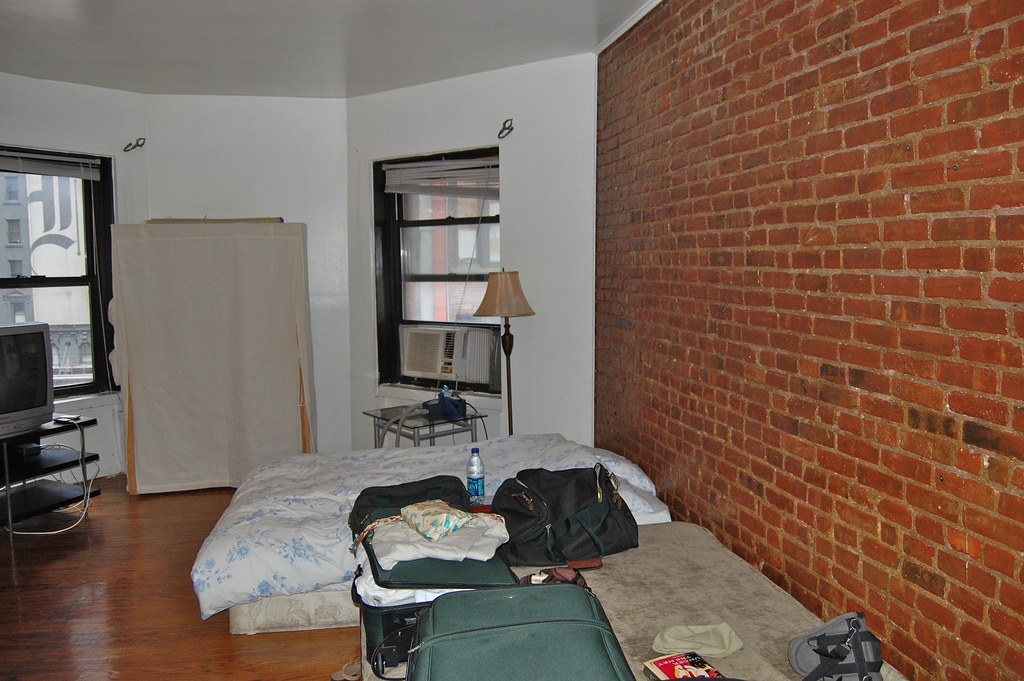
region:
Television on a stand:
[2, 309, 97, 528]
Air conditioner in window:
[371, 150, 502, 395]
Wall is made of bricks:
[593, 1, 1012, 670]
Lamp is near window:
[377, 156, 532, 419]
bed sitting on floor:
[1, 435, 690, 673]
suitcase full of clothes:
[337, 473, 519, 670]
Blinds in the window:
[365, 150, 502, 391]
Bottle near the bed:
[462, 441, 485, 509]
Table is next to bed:
[225, 387, 672, 629]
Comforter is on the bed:
[190, 432, 675, 635]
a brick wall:
[709, 136, 1011, 418]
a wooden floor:
[82, 579, 168, 677]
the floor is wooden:
[73, 570, 156, 676]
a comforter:
[259, 491, 332, 571]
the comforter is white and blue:
[241, 482, 302, 560]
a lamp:
[474, 269, 532, 324]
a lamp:
[470, 264, 548, 432]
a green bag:
[508, 471, 617, 548]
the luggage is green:
[431, 589, 594, 679]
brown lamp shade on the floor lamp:
[476, 265, 535, 322]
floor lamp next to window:
[470, 265, 538, 437]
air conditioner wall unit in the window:
[395, 316, 509, 393]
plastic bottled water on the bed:
[464, 446, 490, 503]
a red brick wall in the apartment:
[596, 2, 1023, 651]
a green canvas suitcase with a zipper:
[408, 582, 639, 678]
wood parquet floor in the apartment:
[85, 496, 193, 678]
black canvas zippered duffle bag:
[486, 461, 642, 566]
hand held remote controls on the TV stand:
[53, 411, 82, 425]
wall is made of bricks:
[593, 4, 999, 612]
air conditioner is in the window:
[354, 303, 514, 381]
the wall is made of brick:
[592, 3, 1022, 680]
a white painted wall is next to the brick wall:
[349, 55, 593, 455]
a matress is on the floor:
[197, 431, 666, 643]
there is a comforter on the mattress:
[187, 430, 671, 617]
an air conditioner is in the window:
[393, 320, 504, 394]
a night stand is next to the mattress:
[364, 398, 485, 449]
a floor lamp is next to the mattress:
[478, 269, 536, 434]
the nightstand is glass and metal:
[359, 396, 487, 436]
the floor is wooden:
[4, 471, 363, 680]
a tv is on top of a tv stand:
[0, 322, 86, 588]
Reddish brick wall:
[593, 0, 1018, 675]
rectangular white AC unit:
[398, 322, 497, 386]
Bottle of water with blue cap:
[464, 443, 488, 500]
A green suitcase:
[401, 578, 637, 677]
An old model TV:
[0, 320, 59, 438]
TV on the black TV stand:
[0, 319, 105, 547]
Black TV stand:
[6, 408, 104, 548]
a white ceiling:
[2, 4, 666, 100]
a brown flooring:
[5, 468, 357, 678]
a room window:
[368, 160, 515, 383]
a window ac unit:
[397, 319, 489, 378]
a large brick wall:
[576, 0, 1022, 679]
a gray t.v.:
[0, 319, 64, 428]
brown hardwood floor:
[0, 480, 351, 678]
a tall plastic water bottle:
[463, 443, 486, 502]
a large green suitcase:
[399, 582, 625, 677]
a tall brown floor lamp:
[472, 258, 534, 424]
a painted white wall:
[346, 62, 602, 459]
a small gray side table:
[364, 401, 492, 456]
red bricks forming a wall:
[601, 56, 681, 143]